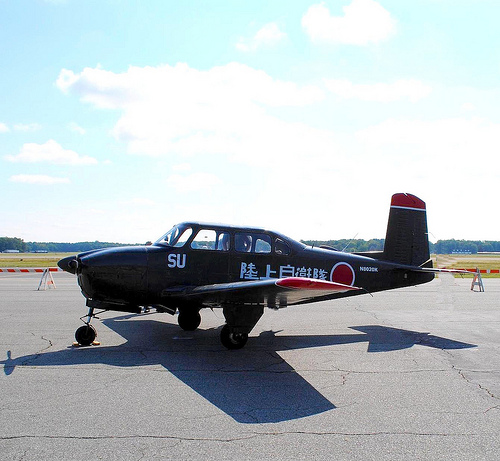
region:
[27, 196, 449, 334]
old plane on runway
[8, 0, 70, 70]
white clouds in blue sky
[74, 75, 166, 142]
white clouds in blue sky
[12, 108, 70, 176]
white clouds in blue sky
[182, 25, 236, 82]
white clouds in blue sky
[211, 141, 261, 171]
white clouds in blue sky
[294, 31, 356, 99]
white clouds in blue sky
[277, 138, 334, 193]
white clouds in blue sky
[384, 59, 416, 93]
white clouds in blue sky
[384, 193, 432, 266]
the tail of a plane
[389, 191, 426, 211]
red tip of the tail of a plane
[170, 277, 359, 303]
a plane's black and red wing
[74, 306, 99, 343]
front landing gear of a plane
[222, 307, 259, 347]
rear landing gear of a plane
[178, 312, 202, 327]
rear landing gear of a plane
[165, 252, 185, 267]
white letters on a plane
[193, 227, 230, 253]
window on a plane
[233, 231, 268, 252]
window on a plane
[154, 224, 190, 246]
window on a plane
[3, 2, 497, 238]
white clouds in sky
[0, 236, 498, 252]
tree tops on horizon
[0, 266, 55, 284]
orange and white barriers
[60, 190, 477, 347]
plane parked on tarmac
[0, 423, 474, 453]
crack in tarmac surface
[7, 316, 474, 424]
shadow of plane on cement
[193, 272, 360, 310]
wing with red tip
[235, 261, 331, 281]
asian characters on plane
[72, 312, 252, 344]
wheels of landing gear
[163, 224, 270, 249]
windows of plane cockpit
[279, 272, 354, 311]
wing of the airplane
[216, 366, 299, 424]
shadow on the ground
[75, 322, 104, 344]
the front wheel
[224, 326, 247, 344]
back wheel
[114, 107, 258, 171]
clouds in the sky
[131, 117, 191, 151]
the sky is cloudy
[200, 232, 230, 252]
a window on the plane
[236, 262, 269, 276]
writing on the plane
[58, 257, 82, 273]
the nose of the plane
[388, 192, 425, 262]
the tail is red and green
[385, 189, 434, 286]
the tail of a plane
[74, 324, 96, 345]
the front wheel of a plane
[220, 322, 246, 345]
the back wheel of a plane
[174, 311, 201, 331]
the back wheel of a plane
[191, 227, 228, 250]
a window on a plane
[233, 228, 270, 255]
a window on a plane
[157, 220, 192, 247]
a cockpit window on a plane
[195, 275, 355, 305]
red and black wing of a plane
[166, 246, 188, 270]
white letters on a plane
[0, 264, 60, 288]
a red and white hazard marker